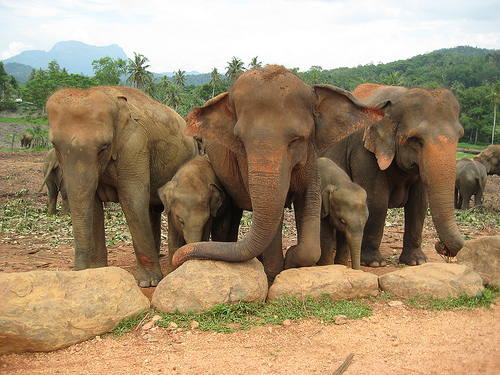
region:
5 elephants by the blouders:
[36, 74, 463, 270]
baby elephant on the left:
[157, 155, 221, 266]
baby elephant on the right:
[320, 158, 366, 268]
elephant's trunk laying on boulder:
[170, 137, 289, 264]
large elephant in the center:
[170, 65, 381, 265]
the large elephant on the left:
[45, 85, 197, 285]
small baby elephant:
[155, 154, 219, 262]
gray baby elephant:
[304, 159, 373, 266]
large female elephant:
[194, 72, 341, 262]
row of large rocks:
[2, 229, 497, 309]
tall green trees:
[8, 62, 498, 119]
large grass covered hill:
[347, 39, 497, 138]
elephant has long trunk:
[172, 148, 293, 269]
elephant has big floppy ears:
[177, 66, 384, 183]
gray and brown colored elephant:
[45, 85, 190, 259]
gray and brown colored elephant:
[206, 58, 339, 277]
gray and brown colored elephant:
[323, 163, 368, 268]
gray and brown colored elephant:
[378, 78, 469, 265]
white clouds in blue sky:
[180, 11, 207, 39]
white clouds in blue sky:
[325, 22, 369, 49]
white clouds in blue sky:
[134, 15, 194, 49]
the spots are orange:
[425, 131, 465, 201]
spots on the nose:
[249, 145, 300, 244]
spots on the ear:
[187, 98, 240, 155]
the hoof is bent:
[288, 232, 315, 277]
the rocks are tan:
[18, 277, 463, 306]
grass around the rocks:
[150, 285, 437, 315]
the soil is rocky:
[148, 320, 378, 370]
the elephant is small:
[170, 168, 245, 259]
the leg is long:
[113, 124, 165, 293]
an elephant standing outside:
[43, 66, 203, 296]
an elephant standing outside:
[161, 140, 236, 248]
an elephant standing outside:
[204, 49, 336, 249]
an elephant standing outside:
[316, 158, 375, 297]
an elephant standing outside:
[343, 63, 480, 297]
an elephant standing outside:
[450, 156, 495, 216]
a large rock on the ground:
[280, 252, 357, 341]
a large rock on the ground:
[392, 248, 482, 344]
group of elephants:
[31, 68, 469, 282]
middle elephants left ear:
[311, 76, 383, 169]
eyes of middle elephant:
[230, 123, 313, 153]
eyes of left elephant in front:
[50, 132, 116, 162]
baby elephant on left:
[160, 156, 225, 277]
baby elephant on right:
[305, 148, 375, 273]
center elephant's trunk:
[170, 160, 300, 271]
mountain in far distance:
[2, 33, 143, 85]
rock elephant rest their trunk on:
[143, 242, 274, 318]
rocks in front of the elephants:
[7, 257, 495, 356]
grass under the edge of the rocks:
[104, 291, 499, 339]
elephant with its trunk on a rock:
[167, 58, 387, 280]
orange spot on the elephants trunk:
[421, 135, 463, 195]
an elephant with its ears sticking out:
[180, 59, 388, 259]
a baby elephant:
[310, 151, 375, 274]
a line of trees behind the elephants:
[1, 54, 498, 144]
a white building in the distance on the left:
[10, 96, 28, 109]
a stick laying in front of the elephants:
[327, 347, 361, 374]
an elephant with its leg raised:
[165, 62, 387, 277]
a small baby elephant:
[159, 156, 224, 265]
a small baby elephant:
[311, 157, 373, 268]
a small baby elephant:
[456, 155, 487, 209]